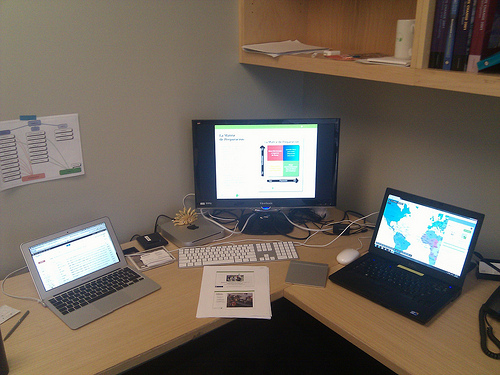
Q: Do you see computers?
A: Yes, there is a computer.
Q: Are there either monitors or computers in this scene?
A: Yes, there is a computer.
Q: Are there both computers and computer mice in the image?
A: Yes, there are both a computer and a computer mouse.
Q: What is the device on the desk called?
A: The device is a computer.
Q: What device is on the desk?
A: The device is a computer.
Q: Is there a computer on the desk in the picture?
A: Yes, there is a computer on the desk.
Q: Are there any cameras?
A: No, there are no cameras.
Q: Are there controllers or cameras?
A: No, there are no cameras or controllers.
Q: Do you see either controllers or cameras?
A: No, there are no cameras or controllers.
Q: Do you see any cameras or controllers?
A: No, there are no cameras or controllers.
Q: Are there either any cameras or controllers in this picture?
A: No, there are no cameras or controllers.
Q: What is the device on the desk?
A: The device is a computer monitor.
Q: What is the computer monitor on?
A: The computer monitor is on the desk.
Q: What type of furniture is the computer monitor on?
A: The computer monitor is on the desk.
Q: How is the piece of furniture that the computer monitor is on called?
A: The piece of furniture is a desk.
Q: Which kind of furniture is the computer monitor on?
A: The computer monitor is on the desk.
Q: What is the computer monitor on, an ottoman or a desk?
A: The computer monitor is on a desk.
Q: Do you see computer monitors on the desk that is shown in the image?
A: Yes, there is a computer monitor on the desk.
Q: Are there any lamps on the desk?
A: No, there is a computer monitor on the desk.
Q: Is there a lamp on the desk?
A: No, there is a computer monitor on the desk.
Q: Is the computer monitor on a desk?
A: Yes, the computer monitor is on a desk.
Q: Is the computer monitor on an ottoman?
A: No, the computer monitor is on a desk.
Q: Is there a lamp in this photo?
A: No, there are no lamps.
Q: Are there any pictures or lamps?
A: No, there are no lamps or pictures.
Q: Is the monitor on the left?
A: Yes, the monitor is on the left of the image.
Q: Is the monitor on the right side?
A: No, the monitor is on the left of the image.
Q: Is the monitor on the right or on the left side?
A: The monitor is on the left of the image.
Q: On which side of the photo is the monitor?
A: The monitor is on the left of the image.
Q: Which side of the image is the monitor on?
A: The monitor is on the left of the image.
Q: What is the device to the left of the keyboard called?
A: The device is a monitor.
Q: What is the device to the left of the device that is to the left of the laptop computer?
A: The device is a monitor.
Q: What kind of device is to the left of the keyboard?
A: The device is a monitor.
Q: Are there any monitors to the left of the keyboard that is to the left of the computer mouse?
A: Yes, there is a monitor to the left of the keyboard.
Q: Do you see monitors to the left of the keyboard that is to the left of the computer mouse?
A: Yes, there is a monitor to the left of the keyboard.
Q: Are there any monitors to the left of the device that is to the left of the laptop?
A: Yes, there is a monitor to the left of the keyboard.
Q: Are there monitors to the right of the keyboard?
A: No, the monitor is to the left of the keyboard.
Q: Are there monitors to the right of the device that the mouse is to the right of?
A: No, the monitor is to the left of the keyboard.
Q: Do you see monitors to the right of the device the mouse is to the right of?
A: No, the monitor is to the left of the keyboard.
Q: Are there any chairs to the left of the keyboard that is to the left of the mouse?
A: No, there is a monitor to the left of the keyboard.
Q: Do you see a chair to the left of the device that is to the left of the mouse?
A: No, there is a monitor to the left of the keyboard.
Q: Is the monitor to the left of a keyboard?
A: Yes, the monitor is to the left of a keyboard.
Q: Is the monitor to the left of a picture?
A: No, the monitor is to the left of a keyboard.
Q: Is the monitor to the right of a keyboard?
A: No, the monitor is to the left of a keyboard.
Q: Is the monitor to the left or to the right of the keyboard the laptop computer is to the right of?
A: The monitor is to the left of the keyboard.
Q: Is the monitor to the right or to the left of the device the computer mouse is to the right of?
A: The monitor is to the left of the keyboard.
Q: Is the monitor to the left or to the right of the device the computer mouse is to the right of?
A: The monitor is to the left of the keyboard.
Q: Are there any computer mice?
A: Yes, there is a computer mouse.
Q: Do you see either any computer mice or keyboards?
A: Yes, there is a computer mouse.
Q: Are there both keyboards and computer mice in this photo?
A: Yes, there are both a computer mouse and a keyboard.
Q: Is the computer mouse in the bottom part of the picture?
A: Yes, the computer mouse is in the bottom of the image.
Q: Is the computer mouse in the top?
A: No, the computer mouse is in the bottom of the image.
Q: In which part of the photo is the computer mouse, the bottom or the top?
A: The computer mouse is in the bottom of the image.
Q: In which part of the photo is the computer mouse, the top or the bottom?
A: The computer mouse is in the bottom of the image.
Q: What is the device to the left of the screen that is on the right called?
A: The device is a computer mouse.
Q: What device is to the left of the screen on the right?
A: The device is a computer mouse.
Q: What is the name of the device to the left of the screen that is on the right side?
A: The device is a computer mouse.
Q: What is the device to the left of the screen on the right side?
A: The device is a computer mouse.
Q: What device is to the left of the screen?
A: The device is a computer mouse.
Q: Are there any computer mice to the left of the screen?
A: Yes, there is a computer mouse to the left of the screen.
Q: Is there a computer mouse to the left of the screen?
A: Yes, there is a computer mouse to the left of the screen.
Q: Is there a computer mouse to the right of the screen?
A: No, the computer mouse is to the left of the screen.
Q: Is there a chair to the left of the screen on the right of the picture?
A: No, there is a computer mouse to the left of the screen.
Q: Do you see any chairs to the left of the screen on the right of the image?
A: No, there is a computer mouse to the left of the screen.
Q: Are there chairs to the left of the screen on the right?
A: No, there is a computer mouse to the left of the screen.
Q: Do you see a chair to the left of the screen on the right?
A: No, there is a computer mouse to the left of the screen.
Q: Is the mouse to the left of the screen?
A: Yes, the mouse is to the left of the screen.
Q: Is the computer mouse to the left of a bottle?
A: No, the computer mouse is to the left of the screen.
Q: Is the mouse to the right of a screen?
A: No, the mouse is to the left of a screen.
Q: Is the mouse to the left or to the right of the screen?
A: The mouse is to the left of the screen.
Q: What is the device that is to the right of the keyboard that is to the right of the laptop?
A: The device is a computer mouse.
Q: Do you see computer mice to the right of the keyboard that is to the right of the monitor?
A: Yes, there is a computer mouse to the right of the keyboard.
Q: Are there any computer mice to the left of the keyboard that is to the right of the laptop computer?
A: No, the computer mouse is to the right of the keyboard.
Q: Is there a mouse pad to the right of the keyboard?
A: No, there is a computer mouse to the right of the keyboard.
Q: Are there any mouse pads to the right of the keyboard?
A: No, there is a computer mouse to the right of the keyboard.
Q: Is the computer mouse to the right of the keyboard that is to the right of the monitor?
A: Yes, the computer mouse is to the right of the keyboard.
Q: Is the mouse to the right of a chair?
A: No, the mouse is to the right of the keyboard.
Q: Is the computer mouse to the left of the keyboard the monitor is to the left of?
A: No, the computer mouse is to the right of the keyboard.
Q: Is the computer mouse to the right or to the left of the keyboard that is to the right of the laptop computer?
A: The computer mouse is to the right of the keyboard.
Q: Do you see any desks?
A: Yes, there is a desk.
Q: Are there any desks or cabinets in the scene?
A: Yes, there is a desk.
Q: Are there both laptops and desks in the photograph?
A: Yes, there are both a desk and a laptop.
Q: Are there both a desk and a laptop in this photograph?
A: Yes, there are both a desk and a laptop.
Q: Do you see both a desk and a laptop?
A: Yes, there are both a desk and a laptop.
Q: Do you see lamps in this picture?
A: No, there are no lamps.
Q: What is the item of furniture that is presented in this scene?
A: The piece of furniture is a desk.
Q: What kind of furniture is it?
A: The piece of furniture is a desk.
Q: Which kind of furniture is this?
A: This is a desk.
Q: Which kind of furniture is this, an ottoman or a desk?
A: This is a desk.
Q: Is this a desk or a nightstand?
A: This is a desk.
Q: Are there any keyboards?
A: Yes, there is a keyboard.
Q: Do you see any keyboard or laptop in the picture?
A: Yes, there is a keyboard.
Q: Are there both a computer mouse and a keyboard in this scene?
A: Yes, there are both a keyboard and a computer mouse.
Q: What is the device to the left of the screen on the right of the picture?
A: The device is a keyboard.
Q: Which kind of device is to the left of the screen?
A: The device is a keyboard.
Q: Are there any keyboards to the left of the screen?
A: Yes, there is a keyboard to the left of the screen.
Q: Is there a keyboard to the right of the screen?
A: No, the keyboard is to the left of the screen.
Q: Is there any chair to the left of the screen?
A: No, there is a keyboard to the left of the screen.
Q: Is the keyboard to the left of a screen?
A: Yes, the keyboard is to the left of a screen.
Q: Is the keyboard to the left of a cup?
A: No, the keyboard is to the left of a screen.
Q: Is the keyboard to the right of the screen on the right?
A: No, the keyboard is to the left of the screen.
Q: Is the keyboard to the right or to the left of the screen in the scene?
A: The keyboard is to the left of the screen.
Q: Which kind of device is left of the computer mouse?
A: The device is a keyboard.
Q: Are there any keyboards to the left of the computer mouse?
A: Yes, there is a keyboard to the left of the computer mouse.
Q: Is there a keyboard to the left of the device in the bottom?
A: Yes, there is a keyboard to the left of the computer mouse.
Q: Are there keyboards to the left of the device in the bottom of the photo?
A: Yes, there is a keyboard to the left of the computer mouse.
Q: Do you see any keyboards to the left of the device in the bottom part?
A: Yes, there is a keyboard to the left of the computer mouse.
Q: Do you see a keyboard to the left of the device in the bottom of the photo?
A: Yes, there is a keyboard to the left of the computer mouse.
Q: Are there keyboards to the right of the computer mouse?
A: No, the keyboard is to the left of the computer mouse.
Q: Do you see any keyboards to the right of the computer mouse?
A: No, the keyboard is to the left of the computer mouse.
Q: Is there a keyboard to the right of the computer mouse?
A: No, the keyboard is to the left of the computer mouse.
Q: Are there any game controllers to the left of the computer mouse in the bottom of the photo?
A: No, there is a keyboard to the left of the computer mouse.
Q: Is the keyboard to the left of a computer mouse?
A: Yes, the keyboard is to the left of a computer mouse.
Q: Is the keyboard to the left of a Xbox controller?
A: No, the keyboard is to the left of a computer mouse.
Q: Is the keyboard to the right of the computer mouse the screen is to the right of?
A: No, the keyboard is to the left of the mouse.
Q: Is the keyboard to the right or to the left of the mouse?
A: The keyboard is to the left of the mouse.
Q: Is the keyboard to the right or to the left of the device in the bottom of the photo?
A: The keyboard is to the left of the mouse.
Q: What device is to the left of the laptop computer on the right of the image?
A: The device is a keyboard.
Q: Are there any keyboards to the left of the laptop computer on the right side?
A: Yes, there is a keyboard to the left of the laptop.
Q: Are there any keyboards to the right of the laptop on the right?
A: No, the keyboard is to the left of the laptop.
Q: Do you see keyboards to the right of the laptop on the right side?
A: No, the keyboard is to the left of the laptop.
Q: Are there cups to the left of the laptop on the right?
A: No, there is a keyboard to the left of the laptop.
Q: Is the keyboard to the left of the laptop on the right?
A: Yes, the keyboard is to the left of the laptop.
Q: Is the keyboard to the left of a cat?
A: No, the keyboard is to the left of the laptop.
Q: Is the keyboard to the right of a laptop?
A: No, the keyboard is to the left of a laptop.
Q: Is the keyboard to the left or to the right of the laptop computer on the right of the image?
A: The keyboard is to the left of the laptop.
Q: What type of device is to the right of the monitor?
A: The device is a keyboard.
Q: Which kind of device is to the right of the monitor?
A: The device is a keyboard.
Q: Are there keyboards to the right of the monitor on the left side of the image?
A: Yes, there is a keyboard to the right of the monitor.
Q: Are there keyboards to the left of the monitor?
A: No, the keyboard is to the right of the monitor.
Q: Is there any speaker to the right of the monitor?
A: No, there is a keyboard to the right of the monitor.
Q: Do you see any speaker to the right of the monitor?
A: No, there is a keyboard to the right of the monitor.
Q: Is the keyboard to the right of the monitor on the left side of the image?
A: Yes, the keyboard is to the right of the monitor.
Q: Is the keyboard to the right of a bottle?
A: No, the keyboard is to the right of the monitor.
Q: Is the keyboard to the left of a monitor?
A: No, the keyboard is to the right of a monitor.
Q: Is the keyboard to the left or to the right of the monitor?
A: The keyboard is to the right of the monitor.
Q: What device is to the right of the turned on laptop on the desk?
A: The device is a keyboard.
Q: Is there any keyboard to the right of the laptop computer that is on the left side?
A: Yes, there is a keyboard to the right of the laptop.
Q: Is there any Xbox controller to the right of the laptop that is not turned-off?
A: No, there is a keyboard to the right of the laptop.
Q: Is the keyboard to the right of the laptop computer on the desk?
A: Yes, the keyboard is to the right of the laptop.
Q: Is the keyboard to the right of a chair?
A: No, the keyboard is to the right of the laptop.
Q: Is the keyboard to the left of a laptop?
A: No, the keyboard is to the right of a laptop.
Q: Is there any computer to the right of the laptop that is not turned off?
A: Yes, there are computers to the right of the laptop computer.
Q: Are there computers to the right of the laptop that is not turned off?
A: Yes, there are computers to the right of the laptop computer.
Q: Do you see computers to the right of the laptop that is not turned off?
A: Yes, there are computers to the right of the laptop computer.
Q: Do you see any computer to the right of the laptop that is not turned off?
A: Yes, there are computers to the right of the laptop computer.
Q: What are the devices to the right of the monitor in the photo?
A: The devices are computers.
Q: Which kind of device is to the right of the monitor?
A: The devices are computers.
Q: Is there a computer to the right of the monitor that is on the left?
A: Yes, there are computers to the right of the monitor.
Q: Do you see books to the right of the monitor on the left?
A: No, there are computers to the right of the monitor.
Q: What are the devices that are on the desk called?
A: The devices are computers.